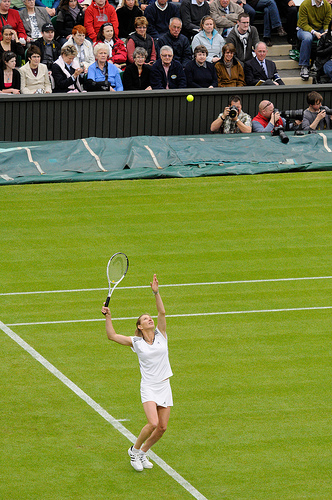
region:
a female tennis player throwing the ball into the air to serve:
[76, 243, 204, 475]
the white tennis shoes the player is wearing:
[122, 442, 161, 474]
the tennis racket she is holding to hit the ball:
[97, 249, 132, 311]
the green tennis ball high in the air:
[181, 88, 198, 106]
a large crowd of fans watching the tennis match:
[4, 1, 327, 91]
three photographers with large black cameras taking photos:
[212, 92, 331, 150]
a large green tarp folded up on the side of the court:
[2, 137, 300, 185]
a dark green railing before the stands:
[7, 93, 173, 136]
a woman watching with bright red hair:
[70, 22, 90, 50]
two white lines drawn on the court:
[189, 275, 317, 334]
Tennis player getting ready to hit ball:
[83, 245, 185, 478]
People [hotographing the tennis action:
[207, 88, 330, 146]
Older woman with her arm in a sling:
[82, 41, 125, 94]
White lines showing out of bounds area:
[183, 275, 242, 318]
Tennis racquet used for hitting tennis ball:
[93, 247, 133, 313]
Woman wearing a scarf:
[49, 42, 85, 93]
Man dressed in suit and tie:
[243, 37, 287, 87]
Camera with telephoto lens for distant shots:
[271, 106, 306, 118]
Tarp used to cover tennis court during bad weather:
[1, 137, 249, 178]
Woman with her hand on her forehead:
[0, 20, 23, 50]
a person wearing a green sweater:
[292, 1, 331, 77]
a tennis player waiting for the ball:
[87, 247, 190, 482]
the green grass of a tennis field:
[189, 255, 330, 484]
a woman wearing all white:
[100, 306, 195, 472]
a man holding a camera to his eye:
[212, 97, 250, 138]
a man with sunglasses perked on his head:
[256, 97, 308, 143]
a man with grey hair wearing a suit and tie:
[250, 41, 285, 83]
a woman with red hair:
[70, 25, 90, 52]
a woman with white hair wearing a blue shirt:
[92, 42, 125, 91]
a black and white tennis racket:
[97, 245, 143, 331]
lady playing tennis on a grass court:
[89, 247, 181, 482]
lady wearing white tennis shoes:
[93, 201, 200, 475]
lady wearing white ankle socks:
[106, 242, 179, 477]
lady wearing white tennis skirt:
[68, 250, 207, 488]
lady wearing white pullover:
[97, 309, 224, 434]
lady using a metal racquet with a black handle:
[77, 224, 186, 474]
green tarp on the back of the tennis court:
[8, 122, 312, 201]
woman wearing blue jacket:
[76, 37, 122, 112]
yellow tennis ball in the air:
[138, 78, 262, 146]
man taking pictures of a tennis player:
[204, 83, 260, 143]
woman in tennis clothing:
[70, 231, 243, 481]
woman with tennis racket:
[81, 224, 246, 440]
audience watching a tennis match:
[0, 32, 304, 130]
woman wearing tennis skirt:
[96, 273, 220, 464]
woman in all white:
[48, 220, 277, 460]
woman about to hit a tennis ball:
[54, 195, 234, 498]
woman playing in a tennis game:
[60, 243, 241, 485]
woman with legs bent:
[59, 259, 237, 498]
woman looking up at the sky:
[40, 202, 200, 441]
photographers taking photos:
[198, 92, 331, 185]